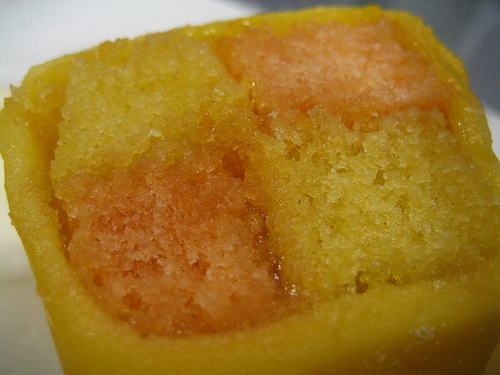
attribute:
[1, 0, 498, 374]
table — white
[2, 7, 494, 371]
corn bread — yellow,  Spongy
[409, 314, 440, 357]
white substance — powdery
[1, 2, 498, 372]
cake — square, moise, yellow, lower, section, orange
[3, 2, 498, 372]
food — orange, patterned, yellow , part, checkered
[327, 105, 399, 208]
food — part, yellow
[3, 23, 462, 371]
cornbread — wet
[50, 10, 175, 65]
plate — white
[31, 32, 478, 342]
food — part, yellow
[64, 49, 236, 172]
cake — upper right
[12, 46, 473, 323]
corn bread —  corn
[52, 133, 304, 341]
cake — section, red, lower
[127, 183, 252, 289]
spot — Hollow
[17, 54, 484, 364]
food — yellow, part